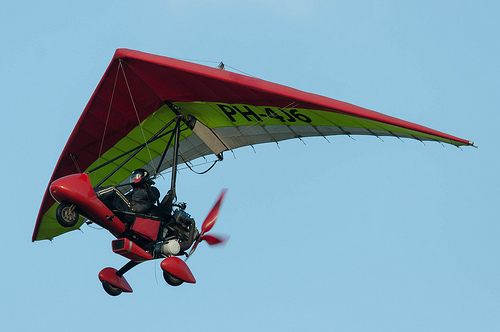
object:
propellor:
[178, 181, 231, 268]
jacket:
[128, 184, 160, 216]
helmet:
[130, 165, 157, 188]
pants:
[93, 183, 130, 209]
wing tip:
[431, 130, 477, 158]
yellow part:
[191, 101, 221, 123]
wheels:
[160, 257, 195, 287]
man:
[124, 165, 161, 219]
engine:
[164, 203, 197, 254]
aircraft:
[30, 49, 478, 296]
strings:
[115, 56, 157, 176]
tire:
[53, 200, 81, 228]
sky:
[1, 0, 500, 330]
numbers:
[261, 104, 314, 121]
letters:
[217, 101, 313, 122]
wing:
[30, 46, 477, 245]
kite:
[31, 48, 477, 241]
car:
[50, 173, 228, 295]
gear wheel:
[98, 266, 133, 295]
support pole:
[166, 122, 183, 206]